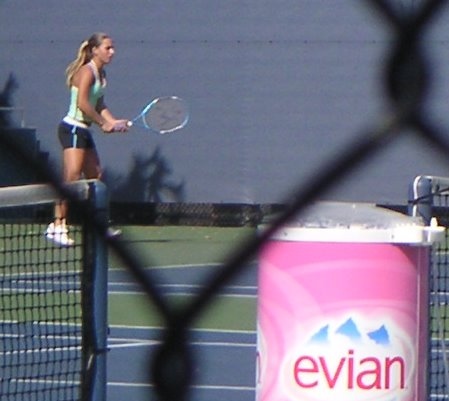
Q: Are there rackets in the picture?
A: Yes, there is a racket.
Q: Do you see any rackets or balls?
A: Yes, there is a racket.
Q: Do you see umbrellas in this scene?
A: No, there are no umbrellas.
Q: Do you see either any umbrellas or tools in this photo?
A: No, there are no umbrellas or tools.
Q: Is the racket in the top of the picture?
A: Yes, the racket is in the top of the image.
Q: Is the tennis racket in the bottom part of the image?
A: No, the tennis racket is in the top of the image.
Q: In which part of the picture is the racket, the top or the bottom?
A: The racket is in the top of the image.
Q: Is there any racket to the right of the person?
A: Yes, there is a racket to the right of the person.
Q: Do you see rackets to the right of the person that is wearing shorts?
A: Yes, there is a racket to the right of the person.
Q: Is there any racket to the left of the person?
A: No, the racket is to the right of the person.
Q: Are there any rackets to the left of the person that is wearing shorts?
A: No, the racket is to the right of the person.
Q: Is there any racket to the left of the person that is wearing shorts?
A: No, the racket is to the right of the person.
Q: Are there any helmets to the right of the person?
A: No, there is a racket to the right of the person.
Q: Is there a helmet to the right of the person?
A: No, there is a racket to the right of the person.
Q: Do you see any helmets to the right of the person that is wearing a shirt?
A: No, there is a racket to the right of the person.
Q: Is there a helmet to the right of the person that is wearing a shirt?
A: No, there is a racket to the right of the person.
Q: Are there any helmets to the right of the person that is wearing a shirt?
A: No, there is a racket to the right of the person.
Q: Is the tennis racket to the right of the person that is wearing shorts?
A: Yes, the tennis racket is to the right of the person.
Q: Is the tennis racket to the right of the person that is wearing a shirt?
A: Yes, the tennis racket is to the right of the person.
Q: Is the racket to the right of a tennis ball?
A: No, the racket is to the right of the person.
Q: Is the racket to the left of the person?
A: No, the racket is to the right of the person.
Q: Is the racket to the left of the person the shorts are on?
A: No, the racket is to the right of the person.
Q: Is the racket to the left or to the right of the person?
A: The racket is to the right of the person.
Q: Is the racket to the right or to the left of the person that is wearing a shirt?
A: The racket is to the right of the person.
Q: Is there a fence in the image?
A: Yes, there is a fence.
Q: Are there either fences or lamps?
A: Yes, there is a fence.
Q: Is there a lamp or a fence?
A: Yes, there is a fence.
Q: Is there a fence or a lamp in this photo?
A: Yes, there is a fence.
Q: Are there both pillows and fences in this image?
A: No, there is a fence but no pillows.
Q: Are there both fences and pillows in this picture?
A: No, there is a fence but no pillows.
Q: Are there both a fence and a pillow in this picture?
A: No, there is a fence but no pillows.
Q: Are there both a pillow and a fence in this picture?
A: No, there is a fence but no pillows.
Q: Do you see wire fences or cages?
A: Yes, there is a wire fence.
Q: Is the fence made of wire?
A: Yes, the fence is made of wire.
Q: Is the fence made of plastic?
A: No, the fence is made of wire.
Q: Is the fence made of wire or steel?
A: The fence is made of wire.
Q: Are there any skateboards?
A: No, there are no skateboards.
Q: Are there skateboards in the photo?
A: No, there are no skateboards.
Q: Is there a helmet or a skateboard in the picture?
A: No, there are no skateboards or helmets.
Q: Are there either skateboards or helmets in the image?
A: No, there are no skateboards or helmets.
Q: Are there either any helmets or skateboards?
A: No, there are no skateboards or helmets.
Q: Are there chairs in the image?
A: No, there are no chairs.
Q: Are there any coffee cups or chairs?
A: No, there are no chairs or coffee cups.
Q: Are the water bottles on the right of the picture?
A: Yes, the water bottles are on the right of the image.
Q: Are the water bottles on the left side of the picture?
A: No, the water bottles are on the right of the image.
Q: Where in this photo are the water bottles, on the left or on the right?
A: The water bottles are on the right of the image.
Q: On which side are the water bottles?
A: The water bottles are on the right of the image.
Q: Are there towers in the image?
A: No, there are no towers.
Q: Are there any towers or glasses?
A: No, there are no towers or glasses.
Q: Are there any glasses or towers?
A: No, there are no towers or glasses.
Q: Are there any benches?
A: No, there are no benches.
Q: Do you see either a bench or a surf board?
A: No, there are no benches or surfboards.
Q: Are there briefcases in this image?
A: No, there are no briefcases.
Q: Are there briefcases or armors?
A: No, there are no briefcases or armors.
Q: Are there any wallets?
A: No, there are no wallets.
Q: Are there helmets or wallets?
A: No, there are no wallets or helmets.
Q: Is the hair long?
A: Yes, the hair is long.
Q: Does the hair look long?
A: Yes, the hair is long.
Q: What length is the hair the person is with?
A: The hair is long.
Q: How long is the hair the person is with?
A: The hair is long.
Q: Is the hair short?
A: No, the hair is long.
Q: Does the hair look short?
A: No, the hair is long.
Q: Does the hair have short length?
A: No, the hair is long.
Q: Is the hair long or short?
A: The hair is long.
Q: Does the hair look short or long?
A: The hair is long.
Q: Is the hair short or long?
A: The hair is long.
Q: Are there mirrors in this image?
A: No, there are no mirrors.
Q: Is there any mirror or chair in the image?
A: No, there are no mirrors or chairs.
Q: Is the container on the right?
A: Yes, the container is on the right of the image.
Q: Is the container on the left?
A: No, the container is on the right of the image.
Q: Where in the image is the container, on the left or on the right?
A: The container is on the right of the image.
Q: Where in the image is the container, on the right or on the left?
A: The container is on the right of the image.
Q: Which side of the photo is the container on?
A: The container is on the right of the image.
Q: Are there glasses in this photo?
A: No, there are no glasses.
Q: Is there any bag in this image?
A: No, there are no bags.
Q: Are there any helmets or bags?
A: No, there are no bags or helmets.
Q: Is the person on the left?
A: Yes, the person is on the left of the image.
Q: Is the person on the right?
A: No, the person is on the left of the image.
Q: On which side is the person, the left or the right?
A: The person is on the left of the image.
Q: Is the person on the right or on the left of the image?
A: The person is on the left of the image.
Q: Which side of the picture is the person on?
A: The person is on the left of the image.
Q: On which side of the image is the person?
A: The person is on the left of the image.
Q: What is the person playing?
A: The person is playing tennis.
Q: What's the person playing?
A: The person is playing tennis.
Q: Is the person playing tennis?
A: Yes, the person is playing tennis.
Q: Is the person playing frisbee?
A: No, the person is playing tennis.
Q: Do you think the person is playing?
A: Yes, the person is playing.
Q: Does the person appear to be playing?
A: Yes, the person is playing.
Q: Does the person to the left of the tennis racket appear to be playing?
A: Yes, the person is playing.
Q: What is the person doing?
A: The person is playing.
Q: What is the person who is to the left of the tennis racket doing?
A: The person is playing.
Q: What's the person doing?
A: The person is playing.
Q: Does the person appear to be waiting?
A: No, the person is playing.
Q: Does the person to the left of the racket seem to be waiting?
A: No, the person is playing.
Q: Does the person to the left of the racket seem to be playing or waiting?
A: The person is playing.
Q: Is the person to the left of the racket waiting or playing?
A: The person is playing.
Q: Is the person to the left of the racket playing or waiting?
A: The person is playing.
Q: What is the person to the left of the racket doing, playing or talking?
A: The person is playing.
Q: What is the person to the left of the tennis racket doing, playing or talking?
A: The person is playing.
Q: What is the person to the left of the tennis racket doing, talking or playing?
A: The person is playing.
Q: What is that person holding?
A: The person is holding the tennis racket.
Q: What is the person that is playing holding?
A: The person is holding the tennis racket.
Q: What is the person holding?
A: The person is holding the tennis racket.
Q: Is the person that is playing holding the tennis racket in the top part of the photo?
A: Yes, the person is holding the racket.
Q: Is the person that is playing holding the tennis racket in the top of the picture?
A: Yes, the person is holding the racket.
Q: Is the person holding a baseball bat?
A: No, the person is holding the racket.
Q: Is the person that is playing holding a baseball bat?
A: No, the person is holding the racket.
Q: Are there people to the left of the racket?
A: Yes, there is a person to the left of the racket.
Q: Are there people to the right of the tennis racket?
A: No, the person is to the left of the tennis racket.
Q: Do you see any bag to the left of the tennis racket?
A: No, there is a person to the left of the tennis racket.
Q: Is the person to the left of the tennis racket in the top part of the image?
A: Yes, the person is to the left of the tennis racket.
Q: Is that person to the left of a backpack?
A: No, the person is to the left of the tennis racket.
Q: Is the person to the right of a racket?
A: No, the person is to the left of a racket.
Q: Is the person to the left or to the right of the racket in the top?
A: The person is to the left of the tennis racket.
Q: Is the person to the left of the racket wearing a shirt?
A: Yes, the person is wearing a shirt.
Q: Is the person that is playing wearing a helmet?
A: No, the person is wearing a shirt.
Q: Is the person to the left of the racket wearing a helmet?
A: No, the person is wearing a shirt.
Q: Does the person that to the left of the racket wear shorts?
A: Yes, the person wears shorts.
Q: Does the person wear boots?
A: No, the person wears shorts.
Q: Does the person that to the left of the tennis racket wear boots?
A: No, the person wears shorts.